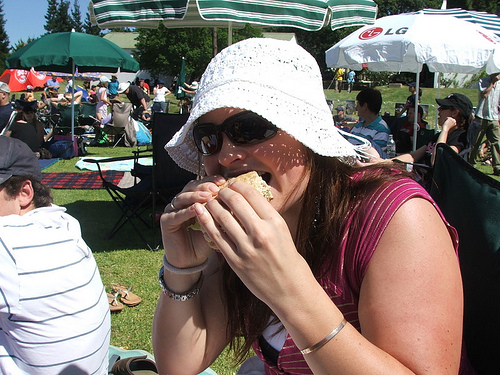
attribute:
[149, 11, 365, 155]
hat — white , lace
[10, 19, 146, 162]
umbrella — green 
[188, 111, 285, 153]
sunglasses — black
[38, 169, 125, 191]
blanket — red, black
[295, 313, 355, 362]
bracelet — shiny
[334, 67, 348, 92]
person — tiny 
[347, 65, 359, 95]
person — tiny 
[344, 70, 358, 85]
shirt — yellow 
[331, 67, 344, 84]
shirt — pastel blue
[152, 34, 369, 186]
white hat — white 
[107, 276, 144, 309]
sandals — brown, leather 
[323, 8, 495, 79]
umbrella — white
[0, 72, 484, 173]
peoples — sitting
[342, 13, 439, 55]
logo — LG 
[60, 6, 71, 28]
leaves — green 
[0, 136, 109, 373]
gentleman — striped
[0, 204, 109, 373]
striped shirt — blue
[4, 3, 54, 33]
sky — blue 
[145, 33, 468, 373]
woman — white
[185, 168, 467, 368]
shirt — pink